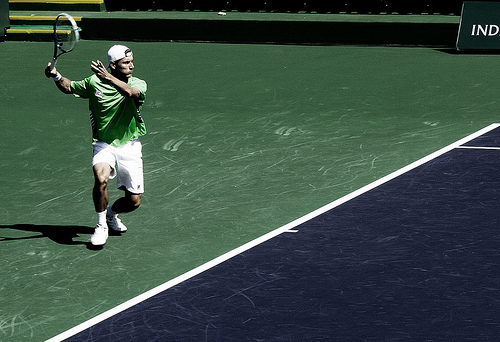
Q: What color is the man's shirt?
A: Green.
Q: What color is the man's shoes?
A: White.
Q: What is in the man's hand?
A: A tennis racquet.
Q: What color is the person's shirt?
A: Green.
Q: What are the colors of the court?
A: Green and blue.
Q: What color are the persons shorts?
A: White.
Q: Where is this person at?
A: Tennis court.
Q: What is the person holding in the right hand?
A: Tennis racket.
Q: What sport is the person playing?
A: Tennis.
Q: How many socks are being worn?
A: Two.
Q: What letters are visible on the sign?
A: Ind.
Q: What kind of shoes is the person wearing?
A: Tennis shoes.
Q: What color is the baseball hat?
A: White.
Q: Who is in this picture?
A: Tennis player.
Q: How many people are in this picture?
A: One.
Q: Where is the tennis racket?
A: In the player's hand.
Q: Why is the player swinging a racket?
A: To hit the ball.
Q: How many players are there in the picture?
A: One.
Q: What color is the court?
A: Blue and green.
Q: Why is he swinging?
A: To hit the ball.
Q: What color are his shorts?
A: White.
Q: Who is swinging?
A: The player.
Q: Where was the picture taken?
A: The tennis court.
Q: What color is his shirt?
A: Green.